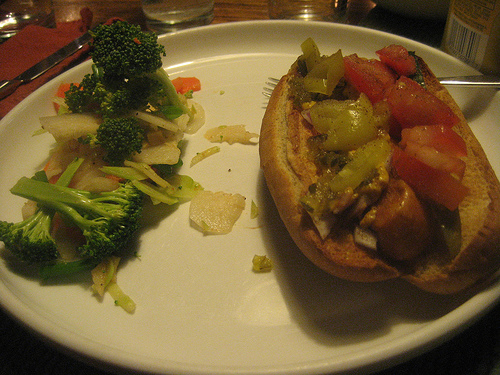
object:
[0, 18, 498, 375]
plate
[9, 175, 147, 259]
broccoli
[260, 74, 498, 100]
fork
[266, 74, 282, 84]
tine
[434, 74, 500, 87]
handle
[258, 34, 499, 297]
sandwich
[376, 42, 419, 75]
tomato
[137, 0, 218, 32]
glass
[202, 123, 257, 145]
food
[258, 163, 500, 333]
shadow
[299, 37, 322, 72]
pepper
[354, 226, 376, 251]
onion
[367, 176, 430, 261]
sausage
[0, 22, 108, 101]
knife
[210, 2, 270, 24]
surface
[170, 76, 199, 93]
carrot